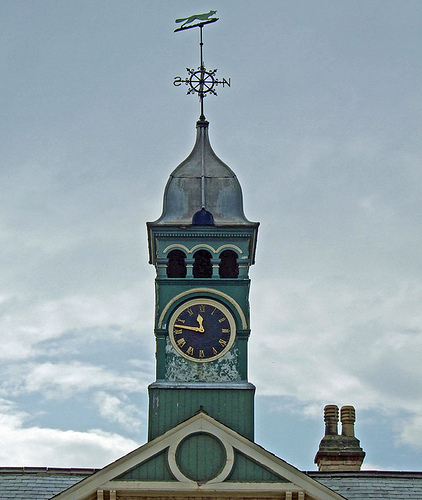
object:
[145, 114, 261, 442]
clock tower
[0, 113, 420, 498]
building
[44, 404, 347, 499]
truss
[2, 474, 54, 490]
shingles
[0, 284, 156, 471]
clouds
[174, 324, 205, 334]
hands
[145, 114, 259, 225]
doom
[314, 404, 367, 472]
chimney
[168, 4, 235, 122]
wind vane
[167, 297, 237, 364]
clock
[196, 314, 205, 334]
hands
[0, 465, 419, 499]
roof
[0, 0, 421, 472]
sky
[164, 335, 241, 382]
paint